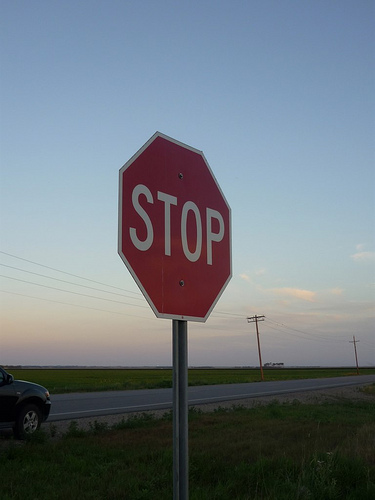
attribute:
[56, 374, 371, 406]
road — long, gray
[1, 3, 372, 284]
sky — clear, blue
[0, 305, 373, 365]
clouds — gray, hazy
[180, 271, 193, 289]
bolt — small , metal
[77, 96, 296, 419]
pole — grey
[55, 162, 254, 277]
white line — faint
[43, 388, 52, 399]
parking light — orange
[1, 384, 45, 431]
car — dark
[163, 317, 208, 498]
post — metal, large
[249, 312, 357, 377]
poles — large, grey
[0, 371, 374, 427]
road — dark grey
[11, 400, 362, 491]
grass — green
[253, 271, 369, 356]
clouds — layered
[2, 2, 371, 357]
sky — blue, pink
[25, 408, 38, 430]
rim — silver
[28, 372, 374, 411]
road — tarmacked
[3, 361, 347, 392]
field — green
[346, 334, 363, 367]
post — electrical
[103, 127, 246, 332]
sign — large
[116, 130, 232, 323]
sign — red, white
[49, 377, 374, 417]
line — white